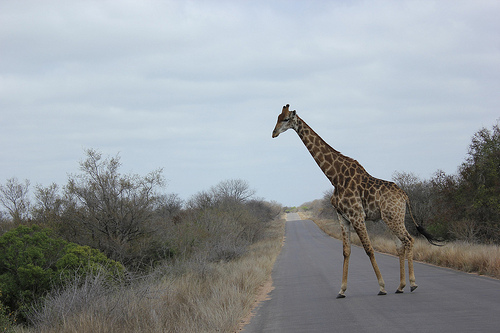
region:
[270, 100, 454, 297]
A brown and white giraffe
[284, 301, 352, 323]
A grey paved ground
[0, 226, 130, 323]
A green bush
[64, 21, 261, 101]
A cloudy sky above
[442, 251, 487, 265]
tall yellow grass on the side of the road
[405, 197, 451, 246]
a giraffe tail with black hairs on the end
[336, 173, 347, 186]
A brown spot on giraffe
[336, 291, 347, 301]
black hoof of giraffe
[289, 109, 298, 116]
ear of giraffe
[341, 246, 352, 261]
knee of giraffe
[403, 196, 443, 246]
The tail of the giraffe.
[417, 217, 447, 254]
The black hair at the end of the giraffe's tail.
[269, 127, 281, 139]
The giraffe's nose and mouth area.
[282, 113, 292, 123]
The giraffe's right eye.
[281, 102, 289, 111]
The two horns on top of the giraffe's head.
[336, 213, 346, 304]
The giraffe's front left leg.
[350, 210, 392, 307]
The giraffe's front right leg.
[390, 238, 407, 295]
The giraffe's back left leg.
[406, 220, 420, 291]
The giraffe's back right leg.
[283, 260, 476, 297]
The road where the giraffe is standing.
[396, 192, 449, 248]
Giraffe's tail hanging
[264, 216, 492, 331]
Paved road running through wilderness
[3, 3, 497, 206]
Sky filled with clouds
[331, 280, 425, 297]
Giraffe's four feet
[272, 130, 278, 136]
Giraffe's nose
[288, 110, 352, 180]
Giraffe's long neck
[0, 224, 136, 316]
Green bush growing on side of road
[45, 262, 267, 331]
Dry grass on side of road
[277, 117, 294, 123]
Giraffe's left eye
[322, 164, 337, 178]
One of giraffe's spots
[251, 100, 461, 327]
giraffe crossing a street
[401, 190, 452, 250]
swishing tail on a giraffe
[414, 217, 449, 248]
giraffes tail has a black end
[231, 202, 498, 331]
long straight piece of road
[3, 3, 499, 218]
overcast cloudy sky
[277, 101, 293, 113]
horns on a giraffe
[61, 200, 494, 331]
dry grass on the sides of a road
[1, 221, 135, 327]
small green bushes next to a road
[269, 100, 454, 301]
giraffe with brown and beige markings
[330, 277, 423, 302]
hooves on giraffe's legs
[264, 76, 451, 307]
tall giraffe crossing a street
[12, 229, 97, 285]
green scrubby bush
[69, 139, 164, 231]
tree without any leaves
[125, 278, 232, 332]
brown dry grass on the roadside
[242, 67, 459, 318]
giraffe walking across the road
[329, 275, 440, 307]
four hooves on a giraffe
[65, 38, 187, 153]
cloudy grey overcast sky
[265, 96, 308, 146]
head on a tall giraffe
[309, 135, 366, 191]
brown spots on a giraffe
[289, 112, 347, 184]
tall long giraffe neck